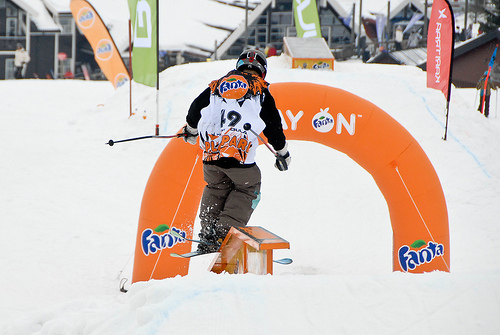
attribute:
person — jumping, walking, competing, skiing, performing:
[180, 47, 290, 250]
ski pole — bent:
[105, 131, 191, 148]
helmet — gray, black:
[237, 48, 268, 76]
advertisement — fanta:
[219, 74, 248, 99]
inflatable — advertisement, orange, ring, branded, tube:
[134, 81, 451, 282]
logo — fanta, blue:
[398, 241, 443, 272]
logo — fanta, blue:
[141, 223, 187, 255]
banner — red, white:
[427, 1, 451, 98]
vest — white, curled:
[195, 69, 264, 166]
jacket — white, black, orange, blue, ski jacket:
[186, 69, 286, 168]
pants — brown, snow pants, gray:
[199, 162, 260, 242]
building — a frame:
[210, 0, 381, 63]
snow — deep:
[1, 58, 499, 334]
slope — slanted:
[110, 55, 492, 334]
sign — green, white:
[126, 1, 158, 89]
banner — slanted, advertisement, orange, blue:
[71, 0, 131, 89]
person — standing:
[12, 41, 29, 77]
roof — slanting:
[16, 0, 82, 32]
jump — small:
[282, 35, 334, 70]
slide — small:
[210, 225, 292, 274]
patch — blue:
[252, 192, 261, 212]